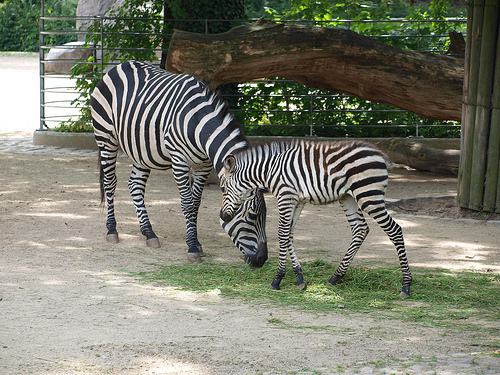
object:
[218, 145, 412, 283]
stripes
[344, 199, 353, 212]
white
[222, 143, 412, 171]
back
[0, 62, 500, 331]
grazing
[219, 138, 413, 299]
walking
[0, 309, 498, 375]
ground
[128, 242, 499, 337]
ground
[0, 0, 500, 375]
enclosure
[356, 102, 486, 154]
ground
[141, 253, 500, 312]
color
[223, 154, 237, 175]
ear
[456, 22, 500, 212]
tree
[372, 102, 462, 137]
leaves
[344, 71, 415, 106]
wood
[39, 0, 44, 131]
pole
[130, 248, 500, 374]
grass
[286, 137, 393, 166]
short mane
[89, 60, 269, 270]
adult zebra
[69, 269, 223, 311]
patch of light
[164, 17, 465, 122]
large wooden branch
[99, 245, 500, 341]
patch of grass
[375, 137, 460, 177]
large log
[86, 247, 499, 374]
grass area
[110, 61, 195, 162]
black strips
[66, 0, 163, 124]
leaves are green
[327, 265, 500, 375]
shadow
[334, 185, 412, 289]
back legs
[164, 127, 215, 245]
legs of the zebra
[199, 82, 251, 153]
mane of the zebra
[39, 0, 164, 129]
fence behind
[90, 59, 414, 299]
zebras are playing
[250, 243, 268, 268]
nose is black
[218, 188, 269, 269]
heads are down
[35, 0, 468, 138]
fence is grey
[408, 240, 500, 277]
sun is on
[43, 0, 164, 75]
big rocks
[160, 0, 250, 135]
big tree